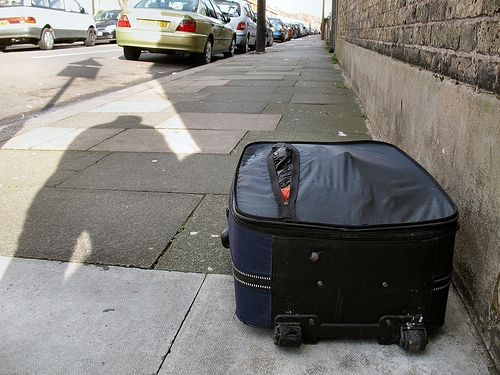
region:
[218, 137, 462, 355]
black and blue and luggage on a sidewalk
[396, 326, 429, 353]
black wheel on a suitcase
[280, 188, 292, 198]
red object peeking from the compartment of suitcase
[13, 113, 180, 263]
person's shadow cast on the ground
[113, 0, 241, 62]
parked vehicle on a street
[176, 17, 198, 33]
red light on the back of a parked vehicle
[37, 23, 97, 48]
two wheels on a vehicle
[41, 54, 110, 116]
sign shadow cast on the street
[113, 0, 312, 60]
line of parked vehicles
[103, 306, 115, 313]
black spot on a ground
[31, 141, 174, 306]
Sidewalk is grey color.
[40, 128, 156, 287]
Sidewalk is made of concrete.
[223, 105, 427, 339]
Suitcase is blue color.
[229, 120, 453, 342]
Suitcase is in sidewalk.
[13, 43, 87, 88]
White lines on road.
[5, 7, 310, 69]
Cars are parked in sides of the road.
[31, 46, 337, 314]
Shadow falls on road.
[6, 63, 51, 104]
road is grey color.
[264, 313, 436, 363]
Wheels are black color.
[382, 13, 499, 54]
wall is made of brick.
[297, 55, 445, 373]
a luggage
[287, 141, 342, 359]
a luggage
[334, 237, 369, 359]
a luggage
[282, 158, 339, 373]
a luggage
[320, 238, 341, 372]
a luggage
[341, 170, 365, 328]
a luggage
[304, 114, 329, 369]
a luggage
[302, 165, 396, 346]
a luggage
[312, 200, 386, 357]
a luggage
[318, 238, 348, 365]
a luggage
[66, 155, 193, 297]
The ground is gray.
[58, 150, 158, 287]
The ground is made of blocks.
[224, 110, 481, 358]
The luggage is blue.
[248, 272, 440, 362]
The luggage has wheels.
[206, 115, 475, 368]
The luggage is open.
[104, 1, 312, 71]
A row of cars.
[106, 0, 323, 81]
The cars are parked.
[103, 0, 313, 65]
The cars are on the side of the street.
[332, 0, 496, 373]
A building is to the right.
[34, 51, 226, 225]
The ground has shadows on it.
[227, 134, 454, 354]
a blue piece of luggage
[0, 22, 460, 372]
a brick paved sidewalk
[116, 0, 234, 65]
a parked lime green car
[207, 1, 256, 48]
a parked white car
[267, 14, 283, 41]
a parked blue car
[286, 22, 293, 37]
a parked red car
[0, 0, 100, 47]
a parked white minivan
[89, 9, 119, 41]
a parked black car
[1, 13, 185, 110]
a paved city street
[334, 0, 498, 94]
a brown brick wall